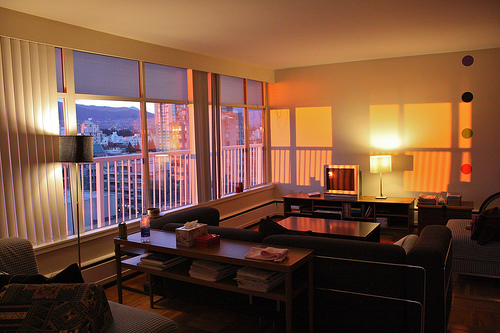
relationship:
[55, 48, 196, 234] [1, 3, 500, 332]
window on apartment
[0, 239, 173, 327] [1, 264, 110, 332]
sofa with items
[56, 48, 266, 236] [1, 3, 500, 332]
view from apartment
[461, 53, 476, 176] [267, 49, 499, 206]
circular discs hanging on wall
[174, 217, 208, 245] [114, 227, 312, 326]
box of tissues on table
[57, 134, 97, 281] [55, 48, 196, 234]
floor lamp close to window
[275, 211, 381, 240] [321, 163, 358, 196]
coffee table opposite television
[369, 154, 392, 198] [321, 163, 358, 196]
lamp near to television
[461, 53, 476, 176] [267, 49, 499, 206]
circular discs on wall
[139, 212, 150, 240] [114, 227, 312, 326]
water bottle on table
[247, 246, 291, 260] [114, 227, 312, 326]
cloth on table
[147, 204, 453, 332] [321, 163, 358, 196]
sofa opposite television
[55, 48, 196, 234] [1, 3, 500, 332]
window in apartment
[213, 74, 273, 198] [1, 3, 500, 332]
window inside apartment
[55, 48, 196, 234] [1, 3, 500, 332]
window inside apartment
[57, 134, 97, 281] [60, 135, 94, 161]
floor lamp with dark shade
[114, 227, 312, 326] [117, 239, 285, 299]
table with shelf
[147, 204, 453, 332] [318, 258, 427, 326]
sofa with metal frame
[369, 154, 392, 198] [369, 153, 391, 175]
lamp with a white shade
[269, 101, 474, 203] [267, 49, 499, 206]
sunset reflected against wall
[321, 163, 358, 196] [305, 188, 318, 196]
television and remote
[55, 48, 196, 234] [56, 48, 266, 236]
window with a city view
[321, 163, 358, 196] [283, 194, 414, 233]
television on top of a table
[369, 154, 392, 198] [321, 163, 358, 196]
lamp next to television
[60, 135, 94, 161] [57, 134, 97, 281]
shade green for floor lamp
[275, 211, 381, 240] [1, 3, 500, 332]
coffee table in center of apartment